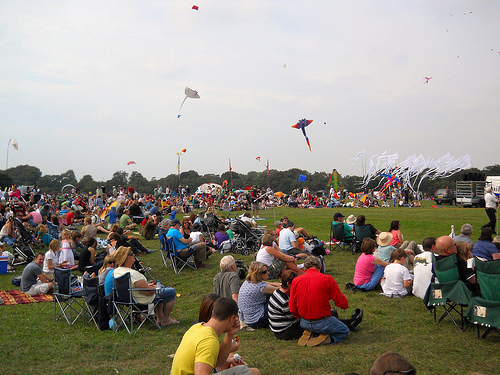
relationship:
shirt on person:
[164, 326, 220, 374] [168, 296, 258, 374]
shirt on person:
[170, 322, 220, 375] [163, 294, 239, 374]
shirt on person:
[170, 322, 220, 375] [177, 300, 238, 372]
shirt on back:
[170, 322, 220, 375] [172, 322, 197, 372]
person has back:
[169, 297, 237, 374] [172, 322, 197, 372]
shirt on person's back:
[284, 268, 352, 321] [290, 265, 332, 319]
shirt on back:
[170, 322, 220, 375] [170, 322, 212, 375]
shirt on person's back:
[170, 322, 220, 375] [170, 323, 210, 366]